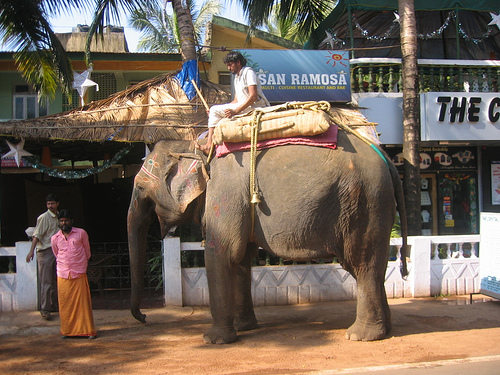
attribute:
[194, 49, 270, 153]
man — sitting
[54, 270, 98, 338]
skirt — orange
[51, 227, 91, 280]
shirt — pink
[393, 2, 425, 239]
tree — palm, slim, behind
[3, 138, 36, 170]
star — white, silver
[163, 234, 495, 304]
fence — white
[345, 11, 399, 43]
tinsel — silver, looped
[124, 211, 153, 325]
trunk — big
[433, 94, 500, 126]
letters — white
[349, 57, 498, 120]
balcony — white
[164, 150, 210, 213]
ear — painted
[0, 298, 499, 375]
ground — dusty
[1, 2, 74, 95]
leaf — palm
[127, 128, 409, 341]
elephant — brown, standing, painted, wrinkly